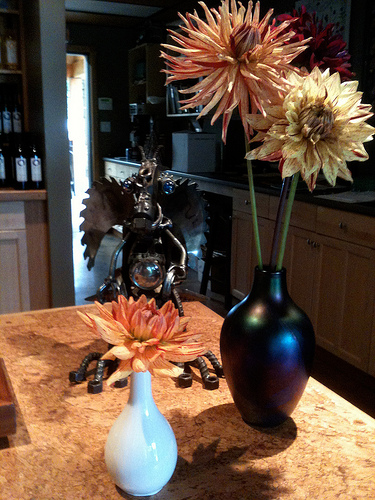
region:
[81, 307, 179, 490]
flower in a vase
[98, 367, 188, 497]
flower vase on a table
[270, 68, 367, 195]
flower in a vase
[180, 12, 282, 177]
flower in a vase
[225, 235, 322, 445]
vase on a table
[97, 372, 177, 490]
vase on a table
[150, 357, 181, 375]
petal of a flower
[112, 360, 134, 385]
petal of a flower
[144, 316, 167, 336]
petal of flower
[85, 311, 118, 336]
petal of a flower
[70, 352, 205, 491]
White small vase on the table.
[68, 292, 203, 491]
Small white vase with red flower.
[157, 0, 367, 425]
Black vase with flowers.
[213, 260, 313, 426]
Black vase on a table.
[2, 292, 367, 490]
Tabletop in orange and brown tone granite.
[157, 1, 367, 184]
Two withering flowers.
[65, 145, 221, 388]
A bizarre black iron decoration.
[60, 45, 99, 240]
Door into the kitchen.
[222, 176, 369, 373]
Wooden bottom kitchen cabinets.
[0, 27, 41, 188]
Wine bottles on the shelves.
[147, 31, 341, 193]
orange and yellow flowers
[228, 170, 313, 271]
green stems on flowers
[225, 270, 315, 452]
flowers in black vase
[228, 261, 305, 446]
vase on brown table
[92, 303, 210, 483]
orange flower in white vase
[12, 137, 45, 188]
wine bottles on table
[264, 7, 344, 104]
red flower in vase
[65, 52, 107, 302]
light shining through doorway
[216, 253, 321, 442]
the vase is black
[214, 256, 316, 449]
the vase is black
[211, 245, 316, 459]
the vase is black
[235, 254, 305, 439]
the vase is black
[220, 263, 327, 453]
the vase is black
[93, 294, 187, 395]
the flower is orange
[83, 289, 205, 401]
the flower is orange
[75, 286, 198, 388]
the flower is orange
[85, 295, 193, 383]
the flower is orange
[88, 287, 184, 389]
the flower is orange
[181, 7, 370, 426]
three flowers in a vase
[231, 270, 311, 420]
vase is dark blue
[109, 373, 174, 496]
light blue smaller vase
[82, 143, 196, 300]
black statue behind vases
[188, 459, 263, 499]
shadow on the table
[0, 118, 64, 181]
bottles in the shelf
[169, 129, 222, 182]
box on the counter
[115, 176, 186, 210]
blue lights on artifact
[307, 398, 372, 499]
table is made of marble